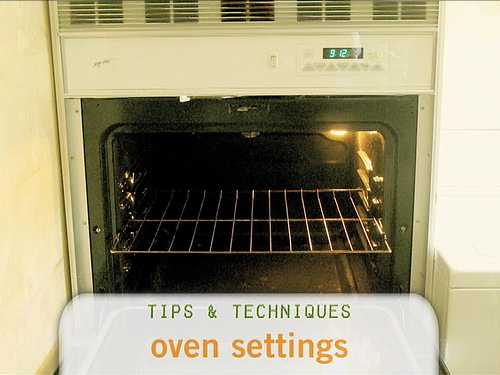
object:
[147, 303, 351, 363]
text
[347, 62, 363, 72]
button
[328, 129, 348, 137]
light on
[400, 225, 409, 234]
screw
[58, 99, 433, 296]
front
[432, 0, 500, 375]
wall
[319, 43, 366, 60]
clock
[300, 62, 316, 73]
button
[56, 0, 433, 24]
vent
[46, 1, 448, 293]
oven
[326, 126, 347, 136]
light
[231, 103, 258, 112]
latch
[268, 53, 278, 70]
switch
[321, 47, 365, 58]
display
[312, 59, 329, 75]
button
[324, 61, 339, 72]
button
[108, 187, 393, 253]
wire grill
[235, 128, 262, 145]
light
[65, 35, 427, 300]
door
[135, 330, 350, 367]
lettering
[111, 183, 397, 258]
rack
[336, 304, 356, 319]
screen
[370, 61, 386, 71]
button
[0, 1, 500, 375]
picture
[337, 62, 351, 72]
button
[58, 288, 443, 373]
background